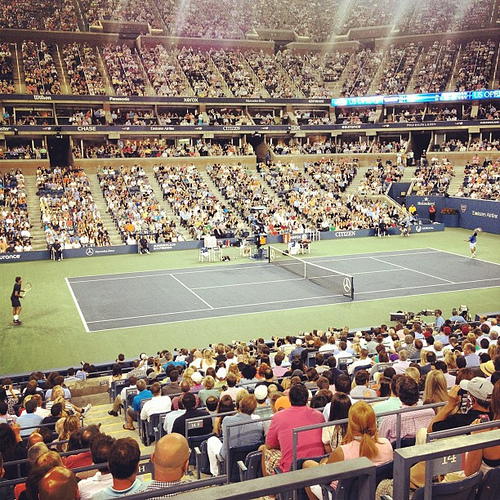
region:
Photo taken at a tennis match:
[12, 165, 492, 377]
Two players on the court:
[5, 207, 498, 320]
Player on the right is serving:
[464, 213, 491, 265]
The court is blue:
[77, 223, 476, 343]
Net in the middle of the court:
[255, 238, 373, 298]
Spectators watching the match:
[6, 316, 476, 493]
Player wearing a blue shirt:
[458, 221, 488, 263]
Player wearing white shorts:
[454, 220, 496, 266]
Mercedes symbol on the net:
[338, 275, 355, 296]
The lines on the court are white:
[57, 244, 474, 334]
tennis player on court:
[458, 221, 485, 258]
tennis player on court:
[0, 277, 32, 327]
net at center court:
[253, 244, 355, 293]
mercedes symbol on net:
[336, 275, 351, 297]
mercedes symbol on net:
[268, 250, 277, 262]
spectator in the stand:
[146, 429, 191, 486]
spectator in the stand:
[331, 398, 386, 458]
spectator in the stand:
[266, 381, 322, 457]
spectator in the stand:
[223, 397, 258, 444]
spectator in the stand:
[388, 375, 432, 430]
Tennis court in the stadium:
[52, 241, 493, 331]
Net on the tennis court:
[261, 238, 358, 303]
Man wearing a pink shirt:
[258, 377, 330, 481]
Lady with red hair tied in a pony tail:
[315, 401, 392, 474]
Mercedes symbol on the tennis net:
[336, 273, 356, 296]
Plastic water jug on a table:
[200, 232, 222, 250]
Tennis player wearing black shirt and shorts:
[8, 273, 33, 329]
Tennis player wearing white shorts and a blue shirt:
[461, 223, 488, 263]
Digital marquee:
[329, 84, 499, 104]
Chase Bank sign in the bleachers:
[73, 124, 100, 134]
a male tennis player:
[8, 275, 31, 325]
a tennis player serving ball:
[465, 226, 480, 259]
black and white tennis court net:
[265, 244, 354, 299]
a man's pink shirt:
[267, 405, 324, 466]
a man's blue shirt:
[221, 415, 261, 462]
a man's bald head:
[151, 432, 188, 480]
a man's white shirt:
[140, 395, 170, 420]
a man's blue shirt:
[132, 388, 151, 409]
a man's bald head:
[37, 465, 78, 497]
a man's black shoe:
[104, 409, 117, 416]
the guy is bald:
[148, 425, 203, 477]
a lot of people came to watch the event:
[226, 367, 398, 429]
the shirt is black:
[9, 287, 29, 300]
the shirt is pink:
[341, 435, 389, 458]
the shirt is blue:
[466, 227, 486, 248]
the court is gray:
[99, 294, 157, 306]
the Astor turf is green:
[36, 336, 76, 356]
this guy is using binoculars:
[447, 376, 491, 416]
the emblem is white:
[336, 272, 361, 302]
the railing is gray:
[288, 421, 383, 444]